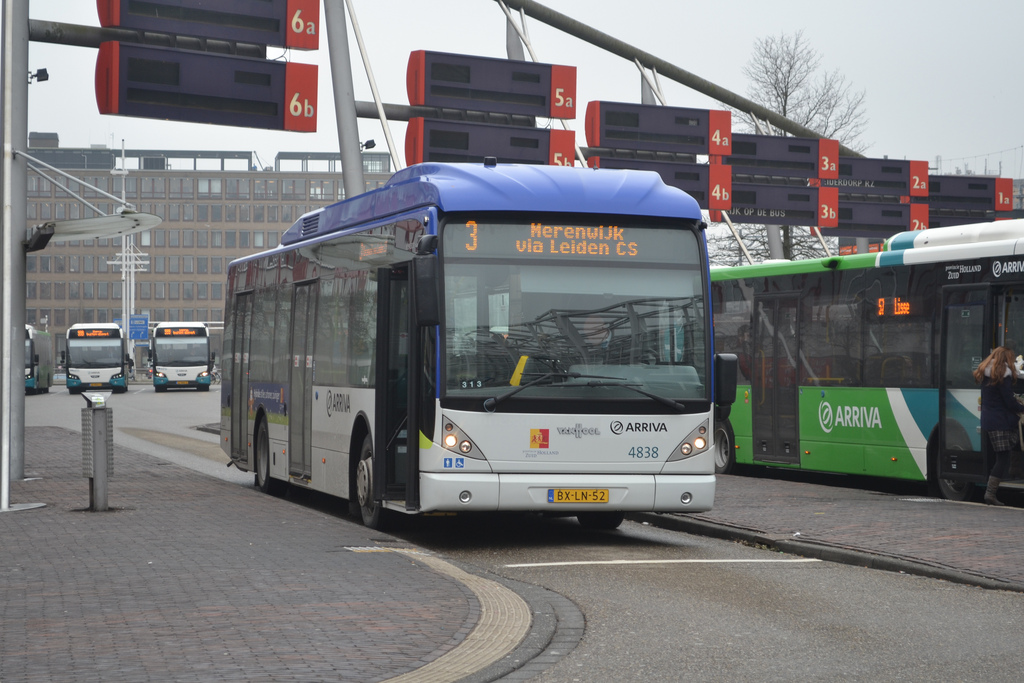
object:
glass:
[441, 214, 707, 404]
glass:
[863, 316, 928, 387]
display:
[444, 218, 706, 267]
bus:
[217, 159, 718, 536]